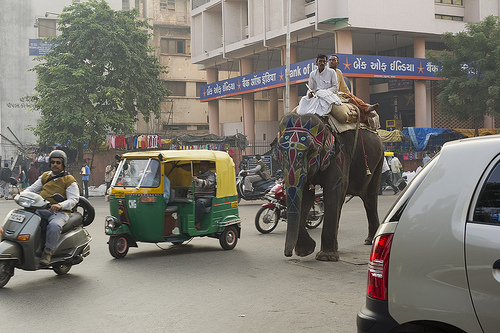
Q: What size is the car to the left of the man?
A: The car is small.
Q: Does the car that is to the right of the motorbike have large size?
A: No, the car is small.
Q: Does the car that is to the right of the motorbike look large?
A: No, the car is small.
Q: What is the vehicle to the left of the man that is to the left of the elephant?
A: The vehicle is a car.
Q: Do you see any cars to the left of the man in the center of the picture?
A: Yes, there is a car to the left of the man.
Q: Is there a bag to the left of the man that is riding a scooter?
A: No, there is a car to the left of the man.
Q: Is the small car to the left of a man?
A: Yes, the car is to the left of a man.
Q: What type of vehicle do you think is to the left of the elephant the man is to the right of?
A: The vehicle is a car.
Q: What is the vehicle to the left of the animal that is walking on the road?
A: The vehicle is a car.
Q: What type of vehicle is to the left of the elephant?
A: The vehicle is a car.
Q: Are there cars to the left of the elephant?
A: Yes, there is a car to the left of the elephant.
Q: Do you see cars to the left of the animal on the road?
A: Yes, there is a car to the left of the elephant.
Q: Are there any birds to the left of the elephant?
A: No, there is a car to the left of the elephant.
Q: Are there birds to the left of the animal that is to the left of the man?
A: No, there is a car to the left of the elephant.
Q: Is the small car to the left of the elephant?
A: Yes, the car is to the left of the elephant.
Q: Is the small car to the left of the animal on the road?
A: Yes, the car is to the left of the elephant.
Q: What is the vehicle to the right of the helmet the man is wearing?
A: The vehicle is a car.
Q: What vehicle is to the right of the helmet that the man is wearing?
A: The vehicle is a car.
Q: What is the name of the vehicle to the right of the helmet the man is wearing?
A: The vehicle is a car.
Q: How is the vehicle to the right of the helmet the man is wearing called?
A: The vehicle is a car.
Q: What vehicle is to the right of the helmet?
A: The vehicle is a car.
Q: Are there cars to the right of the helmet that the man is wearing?
A: Yes, there is a car to the right of the helmet.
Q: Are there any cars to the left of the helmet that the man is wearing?
A: No, the car is to the right of the helmet.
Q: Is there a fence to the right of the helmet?
A: No, there is a car to the right of the helmet.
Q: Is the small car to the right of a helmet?
A: Yes, the car is to the right of a helmet.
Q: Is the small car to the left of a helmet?
A: No, the car is to the right of a helmet.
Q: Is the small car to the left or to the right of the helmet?
A: The car is to the right of the helmet.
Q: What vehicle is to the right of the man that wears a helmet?
A: The vehicle is a car.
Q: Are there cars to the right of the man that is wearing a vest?
A: Yes, there is a car to the right of the man.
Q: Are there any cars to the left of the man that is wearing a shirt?
A: No, the car is to the right of the man.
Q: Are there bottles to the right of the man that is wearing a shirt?
A: No, there is a car to the right of the man.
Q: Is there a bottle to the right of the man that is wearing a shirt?
A: No, there is a car to the right of the man.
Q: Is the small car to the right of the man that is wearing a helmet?
A: Yes, the car is to the right of the man.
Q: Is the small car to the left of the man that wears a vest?
A: No, the car is to the right of the man.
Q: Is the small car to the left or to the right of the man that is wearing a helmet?
A: The car is to the right of the man.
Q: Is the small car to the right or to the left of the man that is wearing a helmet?
A: The car is to the right of the man.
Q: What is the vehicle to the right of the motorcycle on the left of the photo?
A: The vehicle is a car.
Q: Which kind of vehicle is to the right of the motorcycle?
A: The vehicle is a car.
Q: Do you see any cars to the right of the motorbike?
A: Yes, there is a car to the right of the motorbike.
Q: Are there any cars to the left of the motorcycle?
A: No, the car is to the right of the motorcycle.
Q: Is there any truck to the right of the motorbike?
A: No, there is a car to the right of the motorbike.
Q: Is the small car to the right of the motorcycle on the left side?
A: Yes, the car is to the right of the motorbike.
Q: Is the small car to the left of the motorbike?
A: No, the car is to the right of the motorbike.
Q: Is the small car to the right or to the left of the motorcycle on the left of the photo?
A: The car is to the right of the motorbike.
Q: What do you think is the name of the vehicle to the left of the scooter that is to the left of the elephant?
A: The vehicle is a car.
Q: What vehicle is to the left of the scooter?
A: The vehicle is a car.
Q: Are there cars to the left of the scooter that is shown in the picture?
A: Yes, there is a car to the left of the scooter.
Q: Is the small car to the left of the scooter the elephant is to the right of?
A: Yes, the car is to the left of the scooter.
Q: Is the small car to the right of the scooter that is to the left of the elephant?
A: No, the car is to the left of the scooter.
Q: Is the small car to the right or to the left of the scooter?
A: The car is to the left of the scooter.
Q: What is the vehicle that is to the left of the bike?
A: The vehicle is a car.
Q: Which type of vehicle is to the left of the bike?
A: The vehicle is a car.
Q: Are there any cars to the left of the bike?
A: Yes, there is a car to the left of the bike.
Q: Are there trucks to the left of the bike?
A: No, there is a car to the left of the bike.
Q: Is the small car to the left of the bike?
A: Yes, the car is to the left of the bike.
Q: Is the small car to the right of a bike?
A: No, the car is to the left of a bike.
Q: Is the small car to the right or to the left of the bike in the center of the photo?
A: The car is to the left of the bike.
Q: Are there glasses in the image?
A: No, there are no glasses.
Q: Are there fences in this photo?
A: No, there are no fences.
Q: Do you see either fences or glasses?
A: No, there are no fences or glasses.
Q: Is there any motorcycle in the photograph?
A: Yes, there is a motorcycle.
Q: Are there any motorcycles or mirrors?
A: Yes, there is a motorcycle.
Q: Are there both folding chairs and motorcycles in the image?
A: No, there is a motorcycle but no folding chairs.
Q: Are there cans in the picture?
A: No, there are no cans.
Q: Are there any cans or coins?
A: No, there are no cans or coins.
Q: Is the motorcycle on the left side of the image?
A: Yes, the motorcycle is on the left of the image.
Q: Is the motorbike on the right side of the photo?
A: No, the motorbike is on the left of the image.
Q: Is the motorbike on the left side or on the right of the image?
A: The motorbike is on the left of the image.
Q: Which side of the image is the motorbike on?
A: The motorbike is on the left of the image.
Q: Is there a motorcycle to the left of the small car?
A: Yes, there is a motorcycle to the left of the car.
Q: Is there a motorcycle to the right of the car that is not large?
A: No, the motorcycle is to the left of the car.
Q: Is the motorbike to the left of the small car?
A: Yes, the motorbike is to the left of the car.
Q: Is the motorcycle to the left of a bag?
A: No, the motorcycle is to the left of the car.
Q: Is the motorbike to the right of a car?
A: No, the motorbike is to the left of a car.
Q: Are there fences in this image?
A: No, there are no fences.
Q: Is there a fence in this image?
A: No, there are no fences.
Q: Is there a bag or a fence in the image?
A: No, there are no fences or bags.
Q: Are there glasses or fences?
A: No, there are no fences or glasses.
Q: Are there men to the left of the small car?
A: Yes, there is a man to the left of the car.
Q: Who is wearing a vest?
A: The man is wearing a vest.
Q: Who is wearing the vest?
A: The man is wearing a vest.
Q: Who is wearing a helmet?
A: The man is wearing a helmet.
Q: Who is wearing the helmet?
A: The man is wearing a helmet.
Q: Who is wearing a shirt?
A: The man is wearing a shirt.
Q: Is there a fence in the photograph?
A: No, there are no fences.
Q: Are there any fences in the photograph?
A: No, there are no fences.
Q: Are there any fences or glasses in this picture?
A: No, there are no fences or glasses.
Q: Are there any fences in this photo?
A: No, there are no fences.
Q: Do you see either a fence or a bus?
A: No, there are no fences or buses.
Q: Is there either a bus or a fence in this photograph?
A: No, there are no fences or buses.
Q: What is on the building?
A: The sign is on the building.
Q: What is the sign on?
A: The sign is on the building.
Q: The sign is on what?
A: The sign is on the building.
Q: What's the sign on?
A: The sign is on the building.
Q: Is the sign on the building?
A: Yes, the sign is on the building.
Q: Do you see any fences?
A: No, there are no fences.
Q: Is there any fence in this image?
A: No, there are no fences.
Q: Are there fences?
A: No, there are no fences.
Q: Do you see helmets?
A: Yes, there is a helmet.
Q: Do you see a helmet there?
A: Yes, there is a helmet.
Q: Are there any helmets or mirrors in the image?
A: Yes, there is a helmet.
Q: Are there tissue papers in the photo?
A: No, there are no tissue papers.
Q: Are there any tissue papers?
A: No, there are no tissue papers.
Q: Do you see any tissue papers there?
A: No, there are no tissue papers.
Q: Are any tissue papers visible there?
A: No, there are no tissue papers.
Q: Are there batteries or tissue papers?
A: No, there are no tissue papers or batteries.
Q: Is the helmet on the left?
A: Yes, the helmet is on the left of the image.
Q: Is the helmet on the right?
A: No, the helmet is on the left of the image.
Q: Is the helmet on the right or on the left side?
A: The helmet is on the left of the image.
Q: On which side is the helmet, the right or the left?
A: The helmet is on the left of the image.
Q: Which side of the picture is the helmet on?
A: The helmet is on the left of the image.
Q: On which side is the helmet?
A: The helmet is on the left of the image.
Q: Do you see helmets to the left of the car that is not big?
A: Yes, there is a helmet to the left of the car.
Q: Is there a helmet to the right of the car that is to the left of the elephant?
A: No, the helmet is to the left of the car.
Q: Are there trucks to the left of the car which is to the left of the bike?
A: No, there is a helmet to the left of the car.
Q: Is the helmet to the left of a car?
A: Yes, the helmet is to the left of a car.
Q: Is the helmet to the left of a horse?
A: No, the helmet is to the left of a car.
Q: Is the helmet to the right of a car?
A: No, the helmet is to the left of a car.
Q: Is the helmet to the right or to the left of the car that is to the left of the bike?
A: The helmet is to the left of the car.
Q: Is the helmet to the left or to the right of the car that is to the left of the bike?
A: The helmet is to the left of the car.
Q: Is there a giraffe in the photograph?
A: No, there are no giraffes.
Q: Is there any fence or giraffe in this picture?
A: No, there are no giraffes or fences.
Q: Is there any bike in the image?
A: Yes, there is a bike.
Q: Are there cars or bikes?
A: Yes, there is a bike.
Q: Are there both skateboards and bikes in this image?
A: No, there is a bike but no skateboards.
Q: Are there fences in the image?
A: No, there are no fences.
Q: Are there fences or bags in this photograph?
A: No, there are no fences or bags.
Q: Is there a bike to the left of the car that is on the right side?
A: Yes, there is a bike to the left of the car.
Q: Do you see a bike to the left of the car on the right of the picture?
A: Yes, there is a bike to the left of the car.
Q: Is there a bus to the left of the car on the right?
A: No, there is a bike to the left of the car.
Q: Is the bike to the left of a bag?
A: No, the bike is to the left of the car.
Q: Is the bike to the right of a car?
A: No, the bike is to the left of a car.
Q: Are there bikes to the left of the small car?
A: No, the bike is to the right of the car.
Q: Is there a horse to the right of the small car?
A: No, there is a bike to the right of the car.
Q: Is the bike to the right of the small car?
A: Yes, the bike is to the right of the car.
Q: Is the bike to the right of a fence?
A: No, the bike is to the right of the car.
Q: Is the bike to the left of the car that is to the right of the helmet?
A: No, the bike is to the right of the car.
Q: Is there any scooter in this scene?
A: Yes, there is a scooter.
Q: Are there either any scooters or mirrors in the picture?
A: Yes, there is a scooter.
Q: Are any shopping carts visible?
A: No, there are no shopping carts.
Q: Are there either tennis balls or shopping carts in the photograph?
A: No, there are no shopping carts or tennis balls.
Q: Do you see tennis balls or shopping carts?
A: No, there are no shopping carts or tennis balls.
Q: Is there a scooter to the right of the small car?
A: Yes, there is a scooter to the right of the car.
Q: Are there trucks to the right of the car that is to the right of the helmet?
A: No, there is a scooter to the right of the car.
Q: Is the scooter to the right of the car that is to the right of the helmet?
A: Yes, the scooter is to the right of the car.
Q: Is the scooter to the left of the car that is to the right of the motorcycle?
A: No, the scooter is to the right of the car.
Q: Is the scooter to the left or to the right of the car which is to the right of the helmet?
A: The scooter is to the right of the car.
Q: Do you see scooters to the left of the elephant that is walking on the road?
A: Yes, there is a scooter to the left of the elephant.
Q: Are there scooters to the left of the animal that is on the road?
A: Yes, there is a scooter to the left of the elephant.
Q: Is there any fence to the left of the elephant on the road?
A: No, there is a scooter to the left of the elephant.